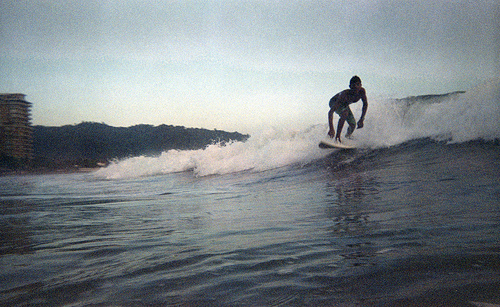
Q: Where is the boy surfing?
A: On the ocean.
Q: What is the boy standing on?
A: Surf board.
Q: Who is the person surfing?
A: A boy.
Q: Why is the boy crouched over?
A: To keep his balance.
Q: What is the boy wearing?
A: Swimming trunks.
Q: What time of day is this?
A: Afternoon.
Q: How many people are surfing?
A: One.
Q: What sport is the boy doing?
A: Surfing.